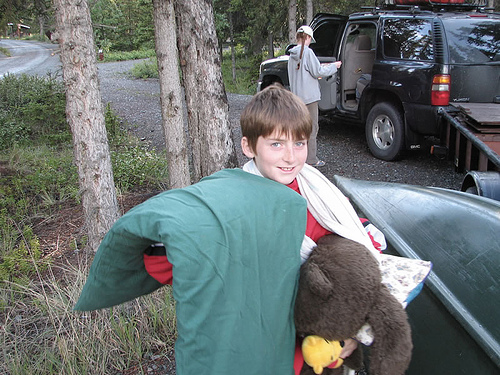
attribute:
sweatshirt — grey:
[287, 47, 337, 104]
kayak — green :
[334, 172, 498, 372]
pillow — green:
[72, 166, 308, 373]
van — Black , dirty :
[257, 2, 497, 164]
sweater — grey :
[275, 25, 348, 114]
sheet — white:
[299, 162, 392, 262]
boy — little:
[136, 77, 421, 373]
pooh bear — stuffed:
[297, 330, 346, 367]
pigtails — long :
[296, 34, 305, 71]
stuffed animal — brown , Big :
[295, 234, 410, 374]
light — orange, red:
[426, 70, 453, 113]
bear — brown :
[281, 230, 412, 361]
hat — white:
[284, 14, 316, 56]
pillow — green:
[91, 177, 315, 347]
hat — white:
[293, 12, 319, 37]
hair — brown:
[240, 82, 316, 157]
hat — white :
[296, 22, 317, 42]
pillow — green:
[162, 188, 293, 364]